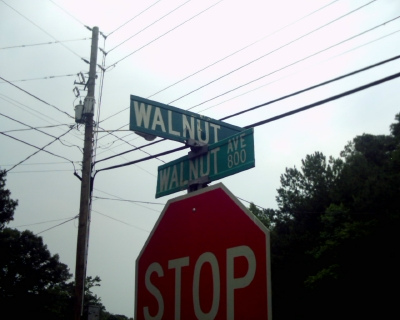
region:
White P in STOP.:
[224, 243, 257, 319]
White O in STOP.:
[191, 252, 219, 317]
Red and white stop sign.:
[133, 182, 273, 318]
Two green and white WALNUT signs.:
[127, 94, 256, 198]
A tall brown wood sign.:
[72, 23, 98, 319]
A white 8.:
[226, 152, 234, 168]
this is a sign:
[133, 84, 226, 144]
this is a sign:
[150, 132, 260, 182]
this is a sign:
[132, 185, 278, 317]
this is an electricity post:
[68, 16, 120, 317]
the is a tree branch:
[275, 149, 315, 217]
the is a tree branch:
[299, 148, 345, 198]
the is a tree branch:
[263, 203, 335, 284]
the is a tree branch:
[12, 215, 54, 288]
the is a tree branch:
[38, 244, 75, 306]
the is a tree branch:
[322, 150, 358, 187]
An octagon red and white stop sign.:
[134, 182, 275, 318]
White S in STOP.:
[142, 261, 164, 318]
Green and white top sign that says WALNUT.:
[128, 94, 241, 146]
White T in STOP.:
[167, 256, 190, 318]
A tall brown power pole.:
[72, 23, 98, 319]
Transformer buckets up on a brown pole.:
[72, 95, 96, 121]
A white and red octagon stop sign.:
[134, 181, 273, 319]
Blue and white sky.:
[0, 1, 398, 201]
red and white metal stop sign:
[134, 180, 274, 318]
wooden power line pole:
[70, 23, 100, 317]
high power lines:
[0, 1, 398, 237]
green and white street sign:
[129, 95, 244, 147]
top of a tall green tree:
[250, 111, 399, 319]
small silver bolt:
[192, 206, 197, 211]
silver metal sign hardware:
[186, 137, 208, 155]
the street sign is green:
[98, 87, 281, 178]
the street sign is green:
[115, 81, 271, 193]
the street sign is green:
[103, 77, 273, 205]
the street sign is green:
[116, 80, 277, 205]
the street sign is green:
[116, 88, 269, 197]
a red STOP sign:
[124, 164, 290, 317]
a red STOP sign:
[125, 189, 283, 313]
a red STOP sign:
[111, 180, 272, 315]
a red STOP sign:
[113, 188, 263, 318]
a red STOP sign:
[123, 187, 272, 318]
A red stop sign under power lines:
[130, 181, 270, 318]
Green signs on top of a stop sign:
[121, 92, 253, 198]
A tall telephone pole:
[77, 17, 101, 318]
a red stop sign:
[132, 184, 270, 318]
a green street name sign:
[128, 93, 241, 149]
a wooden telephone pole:
[70, 24, 98, 317]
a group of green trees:
[248, 112, 398, 316]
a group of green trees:
[0, 168, 121, 318]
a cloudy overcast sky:
[0, 0, 398, 318]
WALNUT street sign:
[127, 95, 240, 147]